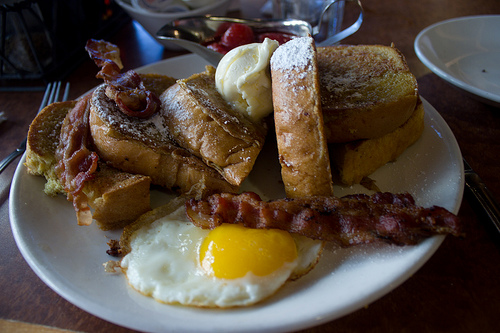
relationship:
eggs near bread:
[113, 201, 303, 309] [166, 31, 425, 191]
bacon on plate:
[187, 188, 456, 249] [11, 38, 466, 330]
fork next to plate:
[4, 80, 74, 204] [11, 38, 466, 330]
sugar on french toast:
[265, 30, 318, 79] [25, 36, 430, 221]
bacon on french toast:
[90, 60, 153, 117] [25, 36, 430, 221]